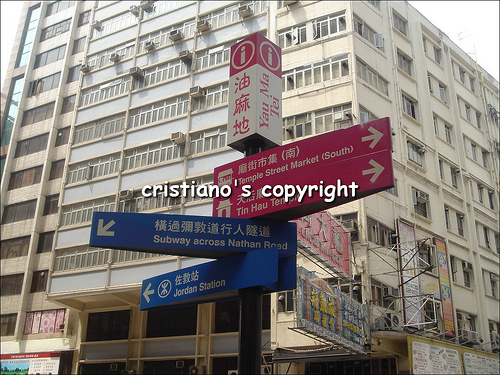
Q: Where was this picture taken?
A: In a city.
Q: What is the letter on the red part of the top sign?
A: I.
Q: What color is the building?
A: White.